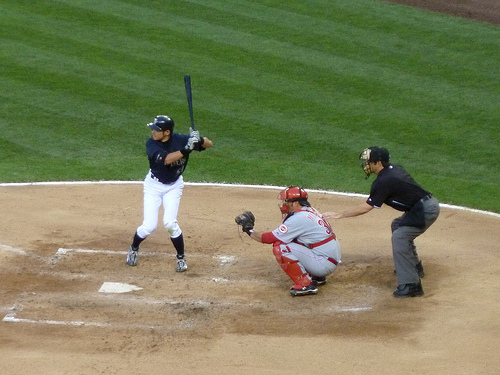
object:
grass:
[0, 0, 499, 206]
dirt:
[1, 184, 496, 374]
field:
[1, 2, 500, 375]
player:
[124, 113, 210, 272]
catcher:
[231, 187, 340, 296]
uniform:
[264, 213, 343, 279]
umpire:
[324, 147, 441, 296]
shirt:
[365, 165, 430, 210]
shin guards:
[273, 242, 310, 291]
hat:
[370, 146, 390, 167]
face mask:
[358, 147, 374, 177]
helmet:
[280, 185, 308, 200]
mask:
[278, 186, 289, 217]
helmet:
[145, 115, 175, 133]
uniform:
[131, 132, 204, 255]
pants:
[138, 169, 185, 240]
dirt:
[168, 228, 175, 236]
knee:
[163, 220, 180, 235]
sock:
[170, 235, 186, 252]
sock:
[132, 230, 145, 250]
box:
[3, 243, 236, 335]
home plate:
[99, 279, 142, 294]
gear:
[279, 187, 312, 296]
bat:
[182, 74, 199, 146]